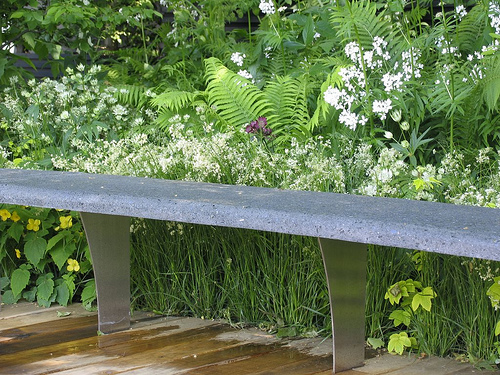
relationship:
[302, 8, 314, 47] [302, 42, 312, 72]
leaf on a stem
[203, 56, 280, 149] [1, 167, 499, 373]
plant behind bench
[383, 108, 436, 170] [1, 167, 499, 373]
plant behind bench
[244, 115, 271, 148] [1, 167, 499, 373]
plant behind bench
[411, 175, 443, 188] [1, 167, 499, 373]
plant behind bench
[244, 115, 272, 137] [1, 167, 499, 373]
plant behind bench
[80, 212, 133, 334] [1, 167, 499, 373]
leg on bench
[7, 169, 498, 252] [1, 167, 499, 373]
seat of bench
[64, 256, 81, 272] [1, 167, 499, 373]
flowers under bench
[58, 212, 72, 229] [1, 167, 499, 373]
flowers under bench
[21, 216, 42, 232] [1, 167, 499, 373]
flowers under bench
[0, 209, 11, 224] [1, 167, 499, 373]
flowers under bench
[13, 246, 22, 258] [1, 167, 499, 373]
flowers under bench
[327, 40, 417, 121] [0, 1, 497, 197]
flowers on bush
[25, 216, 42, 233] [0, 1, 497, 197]
flowers on bush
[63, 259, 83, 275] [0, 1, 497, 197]
flowers on bush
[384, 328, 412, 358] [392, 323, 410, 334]
leaf on stem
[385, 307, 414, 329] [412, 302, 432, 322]
leaf on stem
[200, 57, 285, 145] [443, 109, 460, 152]
leaf on stem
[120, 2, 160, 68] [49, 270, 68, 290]
leaf on stem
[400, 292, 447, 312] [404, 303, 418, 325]
leaf on stem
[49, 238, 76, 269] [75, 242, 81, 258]
leaf on stem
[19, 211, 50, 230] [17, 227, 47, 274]
leaf on stem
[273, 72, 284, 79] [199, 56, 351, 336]
leaf on plant